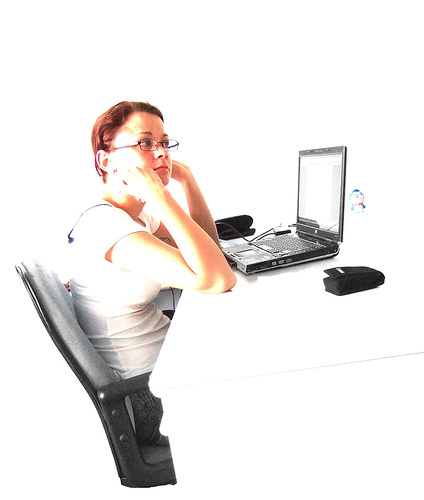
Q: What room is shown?
A: It is an office.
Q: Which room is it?
A: It is an office.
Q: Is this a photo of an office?
A: Yes, it is showing an office.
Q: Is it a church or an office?
A: It is an office.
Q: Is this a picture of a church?
A: No, the picture is showing an office.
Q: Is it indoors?
A: Yes, it is indoors.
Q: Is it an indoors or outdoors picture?
A: It is indoors.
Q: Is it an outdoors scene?
A: No, it is indoors.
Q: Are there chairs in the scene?
A: Yes, there is a chair.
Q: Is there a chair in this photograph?
A: Yes, there is a chair.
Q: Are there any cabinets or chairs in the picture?
A: Yes, there is a chair.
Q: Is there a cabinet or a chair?
A: Yes, there is a chair.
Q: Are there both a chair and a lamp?
A: No, there is a chair but no lamps.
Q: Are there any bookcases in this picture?
A: No, there are no bookcases.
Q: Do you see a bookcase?
A: No, there are no bookcases.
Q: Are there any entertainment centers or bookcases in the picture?
A: No, there are no bookcases or entertainment centers.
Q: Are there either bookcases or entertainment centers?
A: No, there are no bookcases or entertainment centers.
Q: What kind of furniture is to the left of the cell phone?
A: The piece of furniture is a chair.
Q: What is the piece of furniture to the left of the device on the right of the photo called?
A: The piece of furniture is a chair.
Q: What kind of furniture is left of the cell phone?
A: The piece of furniture is a chair.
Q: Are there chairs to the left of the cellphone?
A: Yes, there is a chair to the left of the cellphone.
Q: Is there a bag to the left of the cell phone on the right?
A: No, there is a chair to the left of the cellphone.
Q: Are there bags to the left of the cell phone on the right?
A: No, there is a chair to the left of the cellphone.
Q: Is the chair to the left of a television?
A: No, the chair is to the left of the mobile phone.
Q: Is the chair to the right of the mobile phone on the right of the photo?
A: No, the chair is to the left of the cell phone.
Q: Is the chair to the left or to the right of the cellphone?
A: The chair is to the left of the cellphone.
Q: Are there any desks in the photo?
A: Yes, there is a desk.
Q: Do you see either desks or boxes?
A: Yes, there is a desk.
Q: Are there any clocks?
A: No, there are no clocks.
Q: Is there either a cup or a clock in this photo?
A: No, there are no clocks or cups.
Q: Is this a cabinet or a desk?
A: This is a desk.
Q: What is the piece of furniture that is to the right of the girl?
A: The piece of furniture is a desk.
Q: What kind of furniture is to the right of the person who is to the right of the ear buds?
A: The piece of furniture is a desk.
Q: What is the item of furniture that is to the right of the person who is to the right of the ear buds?
A: The piece of furniture is a desk.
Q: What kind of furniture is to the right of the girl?
A: The piece of furniture is a desk.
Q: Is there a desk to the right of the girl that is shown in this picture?
A: Yes, there is a desk to the right of the girl.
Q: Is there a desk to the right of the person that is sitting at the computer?
A: Yes, there is a desk to the right of the girl.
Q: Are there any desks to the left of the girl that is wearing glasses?
A: No, the desk is to the right of the girl.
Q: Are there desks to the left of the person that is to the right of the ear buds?
A: No, the desk is to the right of the girl.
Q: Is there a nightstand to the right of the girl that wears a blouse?
A: No, there is a desk to the right of the girl.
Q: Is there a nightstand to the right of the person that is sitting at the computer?
A: No, there is a desk to the right of the girl.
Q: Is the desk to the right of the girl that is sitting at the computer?
A: Yes, the desk is to the right of the girl.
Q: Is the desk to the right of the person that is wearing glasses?
A: Yes, the desk is to the right of the girl.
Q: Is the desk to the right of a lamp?
A: No, the desk is to the right of the girl.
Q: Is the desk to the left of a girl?
A: No, the desk is to the right of a girl.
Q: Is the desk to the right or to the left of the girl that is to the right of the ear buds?
A: The desk is to the right of the girl.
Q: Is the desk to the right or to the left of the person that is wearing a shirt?
A: The desk is to the right of the girl.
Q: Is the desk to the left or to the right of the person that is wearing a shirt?
A: The desk is to the right of the girl.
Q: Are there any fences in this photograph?
A: No, there are no fences.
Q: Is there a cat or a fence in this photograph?
A: No, there are no fences or cats.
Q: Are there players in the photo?
A: No, there are no players.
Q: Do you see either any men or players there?
A: No, there are no players or men.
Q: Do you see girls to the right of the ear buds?
A: Yes, there is a girl to the right of the ear buds.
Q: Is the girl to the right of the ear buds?
A: Yes, the girl is to the right of the ear buds.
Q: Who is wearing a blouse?
A: The girl is wearing a blouse.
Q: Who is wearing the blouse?
A: The girl is wearing a blouse.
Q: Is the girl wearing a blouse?
A: Yes, the girl is wearing a blouse.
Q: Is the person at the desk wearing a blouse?
A: Yes, the girl is wearing a blouse.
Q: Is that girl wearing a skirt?
A: No, the girl is wearing a blouse.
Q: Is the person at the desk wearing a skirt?
A: No, the girl is wearing a blouse.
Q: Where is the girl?
A: The girl is at the desk.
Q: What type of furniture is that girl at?
A: The girl is at the desk.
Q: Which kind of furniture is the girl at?
A: The girl is at the desk.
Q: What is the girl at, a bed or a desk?
A: The girl is at a desk.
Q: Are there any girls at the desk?
A: Yes, there is a girl at the desk.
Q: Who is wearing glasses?
A: The girl is wearing glasses.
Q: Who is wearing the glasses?
A: The girl is wearing glasses.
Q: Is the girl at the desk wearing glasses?
A: Yes, the girl is wearing glasses.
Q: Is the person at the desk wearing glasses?
A: Yes, the girl is wearing glasses.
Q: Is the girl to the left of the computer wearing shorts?
A: No, the girl is wearing glasses.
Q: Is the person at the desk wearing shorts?
A: No, the girl is wearing glasses.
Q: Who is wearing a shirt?
A: The girl is wearing a shirt.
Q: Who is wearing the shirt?
A: The girl is wearing a shirt.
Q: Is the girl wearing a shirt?
A: Yes, the girl is wearing a shirt.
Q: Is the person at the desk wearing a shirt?
A: Yes, the girl is wearing a shirt.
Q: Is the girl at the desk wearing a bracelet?
A: No, the girl is wearing a shirt.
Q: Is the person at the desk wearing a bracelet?
A: No, the girl is wearing a shirt.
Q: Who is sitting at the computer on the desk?
A: The girl is sitting at the computer.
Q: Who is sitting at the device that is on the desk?
A: The girl is sitting at the computer.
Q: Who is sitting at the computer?
A: The girl is sitting at the computer.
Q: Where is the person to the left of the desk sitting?
A: The girl is sitting at the computer.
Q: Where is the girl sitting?
A: The girl is sitting at the computer.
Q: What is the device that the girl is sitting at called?
A: The device is a computer.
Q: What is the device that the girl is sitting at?
A: The device is a computer.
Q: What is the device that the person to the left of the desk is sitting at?
A: The device is a computer.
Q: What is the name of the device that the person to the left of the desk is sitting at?
A: The device is a computer.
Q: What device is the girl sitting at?
A: The girl is sitting at the computer.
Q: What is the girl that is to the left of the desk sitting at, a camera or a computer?
A: The girl is sitting at a computer.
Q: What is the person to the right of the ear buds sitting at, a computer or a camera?
A: The girl is sitting at a computer.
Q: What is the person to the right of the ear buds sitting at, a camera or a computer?
A: The girl is sitting at a computer.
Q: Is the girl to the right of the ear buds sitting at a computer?
A: Yes, the girl is sitting at a computer.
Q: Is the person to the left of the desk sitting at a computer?
A: Yes, the girl is sitting at a computer.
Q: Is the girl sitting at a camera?
A: No, the girl is sitting at a computer.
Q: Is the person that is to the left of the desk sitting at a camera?
A: No, the girl is sitting at a computer.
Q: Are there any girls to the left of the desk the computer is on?
A: Yes, there is a girl to the left of the desk.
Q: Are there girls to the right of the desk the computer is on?
A: No, the girl is to the left of the desk.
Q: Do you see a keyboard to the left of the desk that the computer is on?
A: No, there is a girl to the left of the desk.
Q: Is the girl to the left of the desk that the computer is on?
A: Yes, the girl is to the left of the desk.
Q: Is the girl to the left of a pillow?
A: No, the girl is to the left of the desk.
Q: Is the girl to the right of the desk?
A: No, the girl is to the left of the desk.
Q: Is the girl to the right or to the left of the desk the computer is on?
A: The girl is to the left of the desk.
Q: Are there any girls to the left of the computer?
A: Yes, there is a girl to the left of the computer.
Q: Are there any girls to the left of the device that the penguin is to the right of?
A: Yes, there is a girl to the left of the computer.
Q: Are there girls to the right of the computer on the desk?
A: No, the girl is to the left of the computer.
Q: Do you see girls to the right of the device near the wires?
A: No, the girl is to the left of the computer.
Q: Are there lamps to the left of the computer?
A: No, there is a girl to the left of the computer.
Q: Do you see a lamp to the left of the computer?
A: No, there is a girl to the left of the computer.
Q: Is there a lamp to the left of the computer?
A: No, there is a girl to the left of the computer.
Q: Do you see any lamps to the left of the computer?
A: No, there is a girl to the left of the computer.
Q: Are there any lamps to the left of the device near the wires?
A: No, there is a girl to the left of the computer.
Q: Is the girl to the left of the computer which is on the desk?
A: Yes, the girl is to the left of the computer.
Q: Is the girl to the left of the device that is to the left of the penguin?
A: Yes, the girl is to the left of the computer.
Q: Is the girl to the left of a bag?
A: No, the girl is to the left of the computer.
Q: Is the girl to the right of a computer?
A: No, the girl is to the left of a computer.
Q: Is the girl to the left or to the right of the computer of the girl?
A: The girl is to the left of the computer.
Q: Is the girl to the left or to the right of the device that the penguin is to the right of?
A: The girl is to the left of the computer.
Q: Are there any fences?
A: No, there are no fences.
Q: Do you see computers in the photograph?
A: Yes, there is a computer.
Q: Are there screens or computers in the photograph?
A: Yes, there is a computer.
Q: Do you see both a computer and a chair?
A: Yes, there are both a computer and a chair.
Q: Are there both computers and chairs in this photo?
A: Yes, there are both a computer and a chair.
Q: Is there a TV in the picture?
A: No, there are no televisions.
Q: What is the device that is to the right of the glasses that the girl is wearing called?
A: The device is a computer.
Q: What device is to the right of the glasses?
A: The device is a computer.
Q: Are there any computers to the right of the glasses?
A: Yes, there is a computer to the right of the glasses.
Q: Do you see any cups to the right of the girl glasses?
A: No, there is a computer to the right of the glasses.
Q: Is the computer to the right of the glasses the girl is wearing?
A: Yes, the computer is to the right of the glasses.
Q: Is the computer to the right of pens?
A: No, the computer is to the right of the glasses.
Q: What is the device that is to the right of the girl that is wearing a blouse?
A: The device is a computer.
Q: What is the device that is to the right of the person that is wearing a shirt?
A: The device is a computer.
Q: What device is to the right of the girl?
A: The device is a computer.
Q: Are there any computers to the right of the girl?
A: Yes, there is a computer to the right of the girl.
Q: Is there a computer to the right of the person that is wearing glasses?
A: Yes, there is a computer to the right of the girl.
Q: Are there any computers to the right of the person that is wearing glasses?
A: Yes, there is a computer to the right of the girl.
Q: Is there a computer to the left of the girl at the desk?
A: No, the computer is to the right of the girl.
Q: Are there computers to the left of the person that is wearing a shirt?
A: No, the computer is to the right of the girl.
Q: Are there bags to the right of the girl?
A: No, there is a computer to the right of the girl.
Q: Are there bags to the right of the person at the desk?
A: No, there is a computer to the right of the girl.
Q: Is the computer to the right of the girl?
A: Yes, the computer is to the right of the girl.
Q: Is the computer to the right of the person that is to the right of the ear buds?
A: Yes, the computer is to the right of the girl.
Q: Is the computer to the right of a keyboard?
A: No, the computer is to the right of the girl.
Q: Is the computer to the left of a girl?
A: No, the computer is to the right of a girl.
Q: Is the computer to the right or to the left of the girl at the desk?
A: The computer is to the right of the girl.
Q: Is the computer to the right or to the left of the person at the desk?
A: The computer is to the right of the girl.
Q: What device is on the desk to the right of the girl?
A: The device is a computer.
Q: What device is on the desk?
A: The device is a computer.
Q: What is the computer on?
A: The computer is on the desk.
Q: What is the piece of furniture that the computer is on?
A: The piece of furniture is a desk.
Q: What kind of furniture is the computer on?
A: The computer is on the desk.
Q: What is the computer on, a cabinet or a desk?
A: The computer is on a desk.